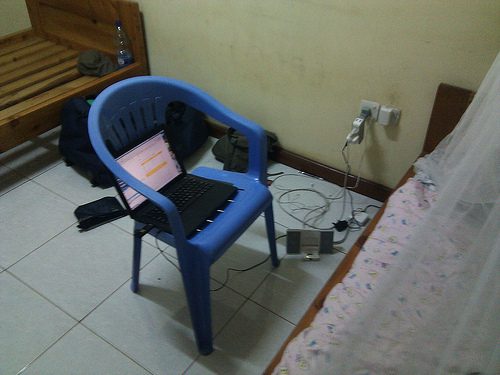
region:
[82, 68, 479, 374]
a blue chair in front a bed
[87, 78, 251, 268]
a laptop over a blue chair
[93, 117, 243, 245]
laptop is black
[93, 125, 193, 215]
screen on of laptop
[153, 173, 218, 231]
keyboard of laptop is black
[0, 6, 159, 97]
a bottle on a bed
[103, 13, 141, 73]
bottle has blue cap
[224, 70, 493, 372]
a brown frame of bed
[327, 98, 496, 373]
a tulle over the bed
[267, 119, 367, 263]
wires on the floor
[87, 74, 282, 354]
a plastic blue chair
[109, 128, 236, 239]
an open laptop computer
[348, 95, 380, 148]
a set of electrical plugs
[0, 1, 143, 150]
a wooden slat bench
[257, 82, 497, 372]
a wooden bench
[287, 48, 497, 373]
a clear white veil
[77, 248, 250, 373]
a white floor tile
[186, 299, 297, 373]
a white floor tile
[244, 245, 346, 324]
a white floor tile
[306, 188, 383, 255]
a white floor tile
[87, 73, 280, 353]
laptop on blue chair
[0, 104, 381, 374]
square tiles on floor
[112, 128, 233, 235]
open laptop with glowing screen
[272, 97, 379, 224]
wires plugged into outlet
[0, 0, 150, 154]
bed frame with no mattress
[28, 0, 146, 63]
plastic bottle against headboard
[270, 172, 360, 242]
wires on white floor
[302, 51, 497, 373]
net canopy over bed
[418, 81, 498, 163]
corner of wood headboard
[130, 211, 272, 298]
wire plugged into laptop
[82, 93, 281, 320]
black laptop on blue chair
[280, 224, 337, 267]
stereo sitting on white tile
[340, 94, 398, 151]
outlet on beige wall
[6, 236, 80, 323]
view of white stone tile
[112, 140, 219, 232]
open black laptop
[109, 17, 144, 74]
water bottle resting against wood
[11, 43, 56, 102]
wood paneling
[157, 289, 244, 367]
plastic blue chair leg on white tile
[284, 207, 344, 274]
small stereo with cords in background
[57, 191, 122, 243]
small black object on white tile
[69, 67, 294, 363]
A blue plastic chair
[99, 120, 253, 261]
a black laptop computer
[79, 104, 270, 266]
A laptop computer on a blue chair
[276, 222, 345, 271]
an iPod plugged into speakers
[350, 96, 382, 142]
A power outlet on a wall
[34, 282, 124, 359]
a white tiled floor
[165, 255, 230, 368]
a blue leg of a chair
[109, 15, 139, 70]
A water bottle on a bed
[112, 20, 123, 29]
A blue bottle cap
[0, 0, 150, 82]
A wooden bed head board